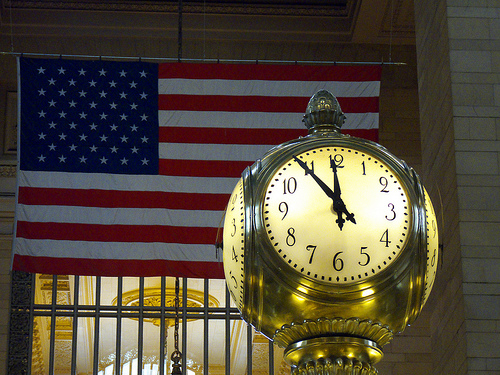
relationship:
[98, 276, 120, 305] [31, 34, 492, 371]
glass window on building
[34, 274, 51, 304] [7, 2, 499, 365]
glass window on building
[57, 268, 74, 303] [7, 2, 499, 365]
glass window on building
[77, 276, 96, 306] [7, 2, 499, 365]
glass window on building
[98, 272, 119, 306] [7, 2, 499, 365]
glass window on building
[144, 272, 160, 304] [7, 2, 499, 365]
glass window on building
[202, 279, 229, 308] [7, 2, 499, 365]
window on building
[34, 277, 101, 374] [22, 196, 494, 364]
window on building